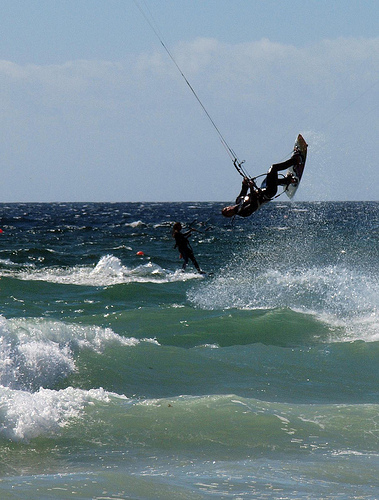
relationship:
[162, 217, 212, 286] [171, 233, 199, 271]
man wearing suit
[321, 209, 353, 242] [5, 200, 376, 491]
waves on water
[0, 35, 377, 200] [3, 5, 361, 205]
clouds are in sky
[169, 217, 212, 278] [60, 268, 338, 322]
man above water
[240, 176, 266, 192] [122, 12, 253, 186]
handlebar attached rope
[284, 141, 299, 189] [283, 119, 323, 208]
feet are on board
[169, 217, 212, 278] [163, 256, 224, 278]
man riding board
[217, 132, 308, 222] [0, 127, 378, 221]
man in mid air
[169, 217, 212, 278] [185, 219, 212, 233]
man holding handle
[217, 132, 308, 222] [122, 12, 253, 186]
man being held rope